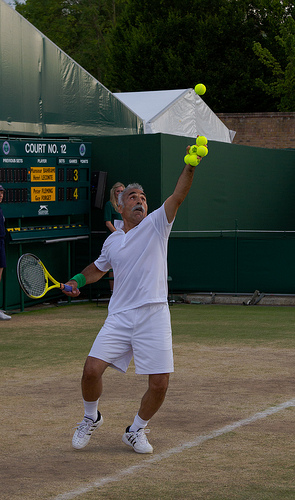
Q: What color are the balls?
A: Green.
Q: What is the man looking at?
A: The balls.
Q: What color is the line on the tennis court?
A: White.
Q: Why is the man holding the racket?
A: He is preparing to hit the balls.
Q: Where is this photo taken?
A: On a tennis court.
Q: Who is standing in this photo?
A: A man.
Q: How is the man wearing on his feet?
A: Tennis shoes.